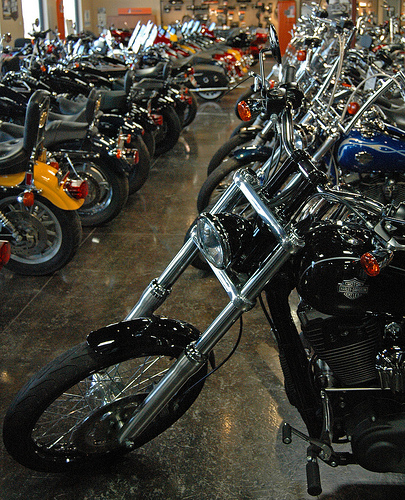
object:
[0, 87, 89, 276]
motorcycle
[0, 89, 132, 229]
motorcycle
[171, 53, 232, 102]
motorcycle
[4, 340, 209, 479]
tire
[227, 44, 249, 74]
back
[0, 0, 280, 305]
motorcycles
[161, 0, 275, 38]
items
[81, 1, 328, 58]
wall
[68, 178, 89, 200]
light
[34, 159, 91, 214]
back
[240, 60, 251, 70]
light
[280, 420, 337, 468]
stick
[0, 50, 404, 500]
floor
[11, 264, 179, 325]
tile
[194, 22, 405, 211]
motorcycle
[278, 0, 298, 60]
door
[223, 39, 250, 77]
motorcycle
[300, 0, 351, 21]
mirror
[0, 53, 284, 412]
isle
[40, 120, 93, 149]
seat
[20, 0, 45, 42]
window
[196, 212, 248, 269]
headlight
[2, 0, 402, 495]
motorcycle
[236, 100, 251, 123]
light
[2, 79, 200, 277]
tires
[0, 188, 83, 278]
tire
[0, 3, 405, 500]
group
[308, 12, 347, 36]
handles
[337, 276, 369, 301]
emblem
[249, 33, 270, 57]
bike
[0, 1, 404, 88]
bikes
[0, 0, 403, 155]
background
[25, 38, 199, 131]
harleys